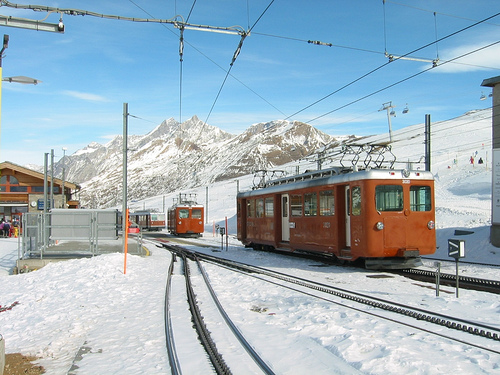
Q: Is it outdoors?
A: Yes, it is outdoors.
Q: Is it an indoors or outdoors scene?
A: It is outdoors.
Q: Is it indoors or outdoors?
A: It is outdoors.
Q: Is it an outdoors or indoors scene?
A: It is outdoors.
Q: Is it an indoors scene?
A: No, it is outdoors.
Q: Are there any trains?
A: Yes, there is a train.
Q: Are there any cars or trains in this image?
A: Yes, there is a train.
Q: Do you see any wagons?
A: No, there are no wagons.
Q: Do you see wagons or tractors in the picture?
A: No, there are no wagons or tractors.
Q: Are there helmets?
A: No, there are no helmets.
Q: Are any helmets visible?
A: No, there are no helmets.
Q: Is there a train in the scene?
A: Yes, there is a train.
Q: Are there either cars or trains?
A: Yes, there is a train.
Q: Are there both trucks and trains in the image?
A: No, there is a train but no trucks.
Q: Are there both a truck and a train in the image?
A: No, there is a train but no trucks.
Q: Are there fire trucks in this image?
A: No, there are no fire trucks.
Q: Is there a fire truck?
A: No, there are no fire trucks.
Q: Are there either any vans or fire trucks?
A: No, there are no fire trucks or vans.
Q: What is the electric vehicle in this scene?
A: The vehicle is a train.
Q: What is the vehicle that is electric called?
A: The vehicle is a train.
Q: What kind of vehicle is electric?
A: The vehicle is a train.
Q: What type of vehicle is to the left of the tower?
A: The vehicle is a train.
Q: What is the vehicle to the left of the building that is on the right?
A: The vehicle is a train.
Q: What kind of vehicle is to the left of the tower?
A: The vehicle is a train.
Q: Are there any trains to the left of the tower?
A: Yes, there is a train to the left of the tower.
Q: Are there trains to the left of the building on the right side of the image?
A: Yes, there is a train to the left of the tower.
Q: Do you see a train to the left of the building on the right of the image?
A: Yes, there is a train to the left of the tower.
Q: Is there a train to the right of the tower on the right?
A: No, the train is to the left of the tower.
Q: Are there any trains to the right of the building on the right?
A: No, the train is to the left of the tower.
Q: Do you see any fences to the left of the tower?
A: No, there is a train to the left of the tower.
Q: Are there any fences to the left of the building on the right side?
A: No, there is a train to the left of the tower.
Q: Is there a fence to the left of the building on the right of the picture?
A: No, there is a train to the left of the tower.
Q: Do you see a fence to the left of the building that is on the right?
A: No, there is a train to the left of the tower.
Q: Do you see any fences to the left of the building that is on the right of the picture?
A: No, there is a train to the left of the tower.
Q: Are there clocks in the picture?
A: No, there are no clocks.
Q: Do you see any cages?
A: No, there are no cages.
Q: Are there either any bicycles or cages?
A: No, there are no cages or bicycles.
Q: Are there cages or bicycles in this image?
A: No, there are no cages or bicycles.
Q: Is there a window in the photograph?
A: Yes, there are windows.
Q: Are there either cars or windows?
A: Yes, there are windows.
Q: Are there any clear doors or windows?
A: Yes, there are clear windows.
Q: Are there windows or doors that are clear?
A: Yes, the windows are clear.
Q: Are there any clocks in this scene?
A: No, there are no clocks.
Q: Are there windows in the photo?
A: Yes, there is a window.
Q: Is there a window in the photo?
A: Yes, there is a window.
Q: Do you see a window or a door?
A: Yes, there is a window.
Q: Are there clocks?
A: No, there are no clocks.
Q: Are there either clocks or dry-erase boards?
A: No, there are no clocks or dry-erase boards.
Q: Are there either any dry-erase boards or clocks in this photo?
A: No, there are no clocks or dry-erase boards.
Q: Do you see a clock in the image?
A: No, there are no clocks.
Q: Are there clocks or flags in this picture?
A: No, there are no clocks or flags.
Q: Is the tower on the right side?
A: Yes, the tower is on the right of the image.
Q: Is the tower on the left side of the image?
A: No, the tower is on the right of the image.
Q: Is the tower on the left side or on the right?
A: The tower is on the right of the image.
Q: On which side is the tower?
A: The tower is on the right of the image.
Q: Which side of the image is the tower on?
A: The tower is on the right of the image.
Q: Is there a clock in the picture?
A: No, there are no clocks.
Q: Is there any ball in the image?
A: No, there are no balls.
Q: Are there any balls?
A: No, there are no balls.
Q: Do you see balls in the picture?
A: No, there are no balls.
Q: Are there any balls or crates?
A: No, there are no balls or crates.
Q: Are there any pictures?
A: No, there are no pictures.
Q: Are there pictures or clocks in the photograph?
A: No, there are no pictures or clocks.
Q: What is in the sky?
A: The clouds are in the sky.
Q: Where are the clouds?
A: The clouds are in the sky.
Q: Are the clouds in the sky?
A: Yes, the clouds are in the sky.